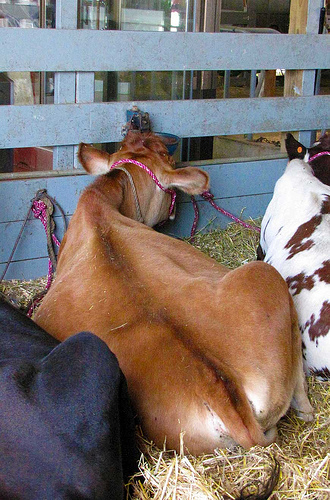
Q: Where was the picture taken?
A: In a barn.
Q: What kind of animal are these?
A: Cows.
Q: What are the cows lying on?
A: Hay.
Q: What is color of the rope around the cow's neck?
A: Pink.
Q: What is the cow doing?
A: Laying down.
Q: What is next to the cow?
A: A wooden fence.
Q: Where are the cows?
A: In the barn.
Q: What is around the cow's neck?
A: A rope.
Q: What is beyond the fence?
A: Windows.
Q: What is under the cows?
A: Hay.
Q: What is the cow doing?
A: Looking at the fence.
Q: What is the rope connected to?
A: The fence.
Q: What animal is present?
A: Cow.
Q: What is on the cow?
A: Brown and white.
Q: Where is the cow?
A: Barn.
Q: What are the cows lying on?
A: Hay.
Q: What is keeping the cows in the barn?
A: Fence.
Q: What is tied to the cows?
A: Rope.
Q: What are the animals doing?
A: Lying there.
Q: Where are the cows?
A: Stall.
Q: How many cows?
A: Three.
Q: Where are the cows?
A: In a barn.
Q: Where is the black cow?
A: On the left.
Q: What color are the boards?
A: Blue.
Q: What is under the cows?
A: Hay.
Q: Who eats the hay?
A: Cows.